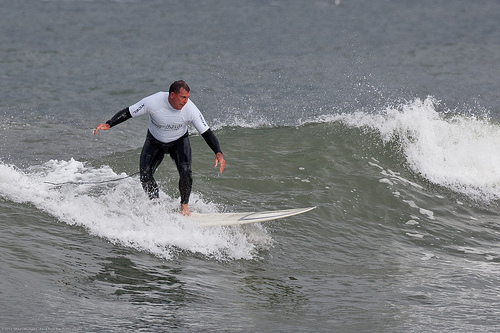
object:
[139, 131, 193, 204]
pants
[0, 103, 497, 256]
wave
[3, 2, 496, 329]
water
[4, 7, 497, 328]
outdoors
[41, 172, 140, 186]
black lead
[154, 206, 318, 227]
surfboard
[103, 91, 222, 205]
wetsuit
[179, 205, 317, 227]
surfboard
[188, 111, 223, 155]
arm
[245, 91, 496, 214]
water wave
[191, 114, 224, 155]
sleeve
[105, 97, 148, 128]
sleeve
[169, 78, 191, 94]
hair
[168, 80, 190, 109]
head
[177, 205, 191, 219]
foot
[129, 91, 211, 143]
shirt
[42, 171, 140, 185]
surfboard leash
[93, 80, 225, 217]
man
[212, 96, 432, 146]
crest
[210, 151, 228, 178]
hand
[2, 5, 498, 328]
scene